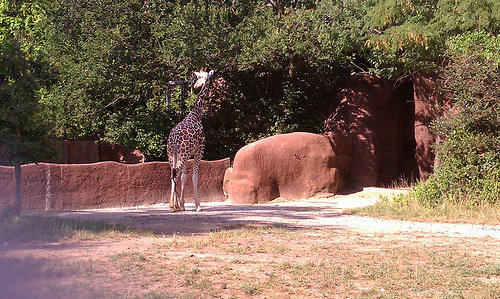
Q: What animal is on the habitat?
A: Giraffe.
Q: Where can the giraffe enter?
A: Small tunnel to the right.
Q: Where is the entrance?
A: On the other side of the gravel pathway.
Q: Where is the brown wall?
A: In front of the giraffe.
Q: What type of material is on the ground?
A: Grass.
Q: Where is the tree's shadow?
A: On the ground.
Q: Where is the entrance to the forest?
A: On the right.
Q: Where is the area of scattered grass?
A: Behind the giraffe.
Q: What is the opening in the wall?
A: Entrance to a cave.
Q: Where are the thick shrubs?
A: Behind the wall.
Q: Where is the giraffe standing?
A: In a habitat.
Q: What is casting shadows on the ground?
A: Trees.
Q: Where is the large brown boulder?
A: By the entrance.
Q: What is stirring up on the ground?
A: Dust.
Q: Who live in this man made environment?
A: Giraffes.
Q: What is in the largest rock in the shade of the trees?
A: A doorway.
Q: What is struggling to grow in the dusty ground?
A: Grass.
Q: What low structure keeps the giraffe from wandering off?
A: An adobe wall.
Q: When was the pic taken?
A: During the day.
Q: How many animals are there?
A: 1.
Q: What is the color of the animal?
A: Brown and white.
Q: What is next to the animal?
A: Stone.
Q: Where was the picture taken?
A: In the zoo.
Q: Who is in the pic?
A: No one.